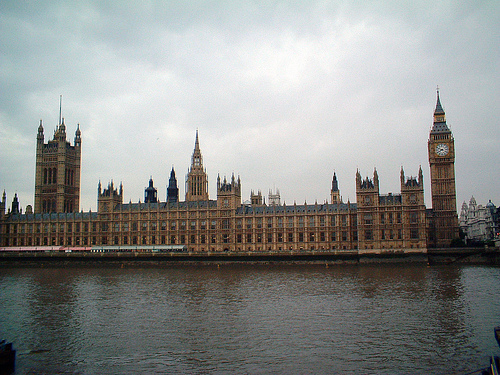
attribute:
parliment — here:
[44, 112, 465, 267]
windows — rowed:
[114, 218, 197, 239]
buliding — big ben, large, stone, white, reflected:
[87, 194, 434, 277]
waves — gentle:
[91, 282, 223, 330]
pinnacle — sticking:
[421, 96, 488, 198]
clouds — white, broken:
[87, 21, 217, 98]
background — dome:
[97, 183, 149, 201]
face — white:
[416, 143, 481, 171]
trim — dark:
[139, 168, 199, 195]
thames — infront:
[272, 270, 418, 363]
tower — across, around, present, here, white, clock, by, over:
[27, 125, 114, 246]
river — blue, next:
[102, 287, 241, 372]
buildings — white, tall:
[455, 200, 497, 237]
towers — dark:
[47, 115, 260, 190]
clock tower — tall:
[390, 97, 459, 210]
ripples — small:
[205, 327, 322, 359]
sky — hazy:
[184, 35, 403, 192]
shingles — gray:
[130, 201, 209, 224]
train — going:
[96, 242, 196, 248]